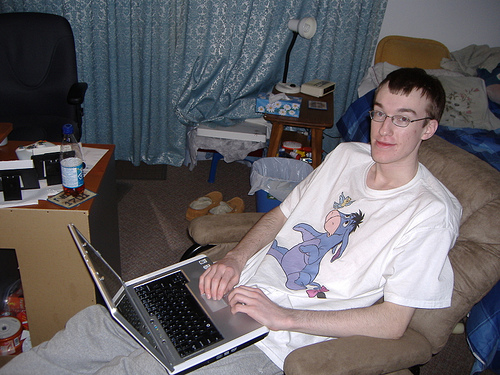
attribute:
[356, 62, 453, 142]
hair — blonde 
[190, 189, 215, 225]
shoe — brown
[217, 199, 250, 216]
shoe — brown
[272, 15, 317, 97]
lamp — white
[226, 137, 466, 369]
t shirt — white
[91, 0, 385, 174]
curtain — blue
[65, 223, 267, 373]
laptop — silver